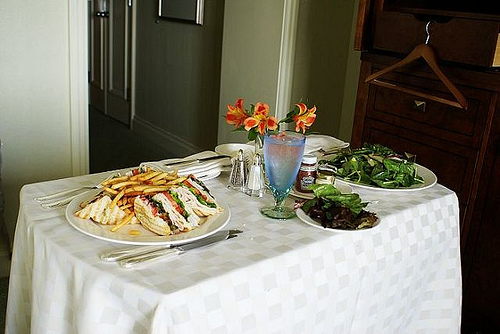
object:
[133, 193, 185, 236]
sandwich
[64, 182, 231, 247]
plate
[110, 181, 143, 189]
fries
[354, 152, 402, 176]
salad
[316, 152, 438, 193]
plate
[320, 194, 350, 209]
salad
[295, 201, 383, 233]
plate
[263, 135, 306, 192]
water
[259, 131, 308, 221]
glass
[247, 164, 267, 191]
salt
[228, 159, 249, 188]
pepper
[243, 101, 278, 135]
flowers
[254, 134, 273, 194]
vase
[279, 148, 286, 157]
light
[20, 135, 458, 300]
table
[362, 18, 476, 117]
hanger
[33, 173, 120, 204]
utensils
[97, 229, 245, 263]
utensils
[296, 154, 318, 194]
bottle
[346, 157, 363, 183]
greens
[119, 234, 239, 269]
knives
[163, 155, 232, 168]
knife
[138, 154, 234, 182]
napkin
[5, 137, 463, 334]
tablecloth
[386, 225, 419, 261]
pattern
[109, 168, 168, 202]
gourmet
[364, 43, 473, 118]
wooden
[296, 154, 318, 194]
jar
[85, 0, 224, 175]
hallway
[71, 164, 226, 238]
food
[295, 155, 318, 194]
condiments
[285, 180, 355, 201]
tray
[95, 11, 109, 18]
silver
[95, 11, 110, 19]
knob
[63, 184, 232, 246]
tray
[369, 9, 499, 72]
drawer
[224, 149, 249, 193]
shaker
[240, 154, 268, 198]
shaker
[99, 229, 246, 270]
pair